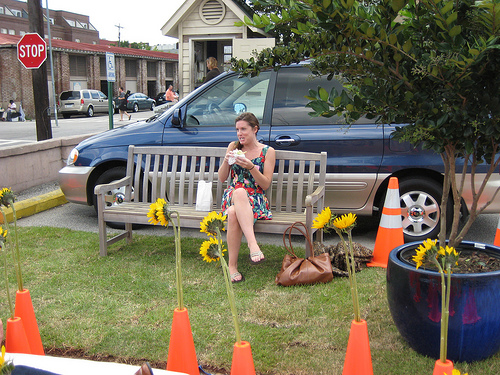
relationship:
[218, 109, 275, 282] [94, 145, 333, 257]
woman sitting on bench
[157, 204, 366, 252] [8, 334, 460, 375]
sunflowers planted in row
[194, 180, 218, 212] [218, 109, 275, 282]
bag next to woman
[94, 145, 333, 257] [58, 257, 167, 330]
bench on top of lawn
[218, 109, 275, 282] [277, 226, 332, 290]
woman has bag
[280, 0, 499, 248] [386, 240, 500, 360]
tree growing inside of flower pot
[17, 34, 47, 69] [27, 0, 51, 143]
stop sign hanging on wooden pole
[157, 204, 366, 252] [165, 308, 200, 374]
sunflowers coming out of traffic cone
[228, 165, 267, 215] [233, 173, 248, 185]
sundress has flowers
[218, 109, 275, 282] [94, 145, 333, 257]
woman sitting on top of bench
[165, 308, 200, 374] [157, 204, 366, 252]
traffic cone holding sunflowers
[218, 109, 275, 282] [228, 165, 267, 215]
woman dressed in sundress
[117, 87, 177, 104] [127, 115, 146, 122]
people walking on sidewalk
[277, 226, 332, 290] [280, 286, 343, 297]
bag on top of grass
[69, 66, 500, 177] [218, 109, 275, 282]
van behind woman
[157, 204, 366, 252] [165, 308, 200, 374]
sunflowers inside of traffic cone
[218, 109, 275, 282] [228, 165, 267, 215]
woman wearing sundress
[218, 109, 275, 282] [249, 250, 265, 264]
woman wearing slippers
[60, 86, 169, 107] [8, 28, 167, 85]
cars parked next to building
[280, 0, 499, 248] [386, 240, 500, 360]
tree inside of flower pot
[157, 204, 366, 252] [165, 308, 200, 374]
sunflowers inside traffic cone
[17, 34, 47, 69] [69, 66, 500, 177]
stop sign in front of van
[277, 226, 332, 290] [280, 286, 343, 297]
bag sitting on top of grass